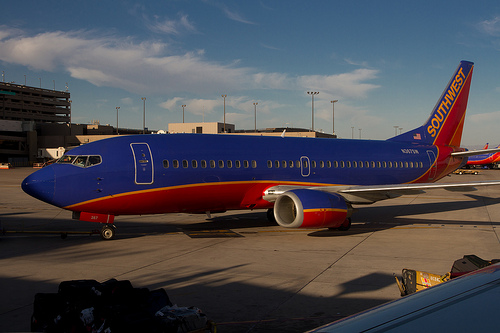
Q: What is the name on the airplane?
A: Southwest.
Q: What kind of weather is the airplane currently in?
A: Sunny.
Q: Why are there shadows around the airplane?
A: The sun is shining.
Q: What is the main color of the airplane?
A: Blue.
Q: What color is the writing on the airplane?
A: Orange.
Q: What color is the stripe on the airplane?
A: Orange.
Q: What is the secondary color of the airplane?
A: Red.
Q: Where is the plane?
A: Airport.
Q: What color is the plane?
A: Blue,red,and yellow.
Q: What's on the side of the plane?
A: Windows.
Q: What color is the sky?
A: Blue.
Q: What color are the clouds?
A: White.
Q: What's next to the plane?
A: Luggage.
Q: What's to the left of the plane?
A: Parking garage.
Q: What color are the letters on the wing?
A: Yellow.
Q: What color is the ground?
A: Grey.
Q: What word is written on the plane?
A: Southwest.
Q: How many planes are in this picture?
A: Two.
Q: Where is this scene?
A: At an airport runway.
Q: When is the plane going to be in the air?
A: Once it takes off.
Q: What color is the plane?
A: It is blue and red.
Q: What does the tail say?
A: Southwest.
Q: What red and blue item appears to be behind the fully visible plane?
A: A second Southwest plane.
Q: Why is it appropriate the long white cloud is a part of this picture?
A: Because it looks like another plane.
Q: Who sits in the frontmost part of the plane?
A: The pilot and co-pilot.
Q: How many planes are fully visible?
A: One.